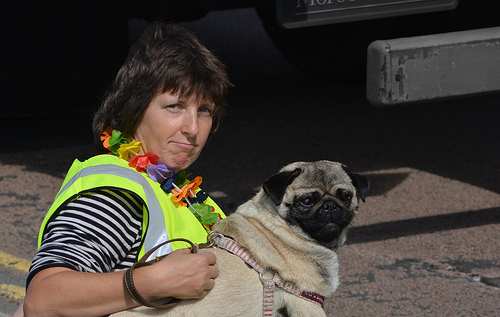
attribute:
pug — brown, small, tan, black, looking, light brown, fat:
[108, 159, 370, 316]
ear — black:
[262, 168, 302, 205]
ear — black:
[342, 164, 369, 204]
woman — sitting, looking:
[22, 21, 227, 316]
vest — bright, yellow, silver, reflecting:
[38, 155, 227, 262]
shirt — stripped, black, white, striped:
[27, 187, 145, 281]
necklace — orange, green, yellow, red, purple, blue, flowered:
[102, 126, 222, 226]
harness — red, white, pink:
[208, 233, 325, 314]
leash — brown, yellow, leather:
[124, 237, 198, 311]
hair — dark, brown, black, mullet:
[93, 24, 234, 139]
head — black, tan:
[269, 160, 367, 240]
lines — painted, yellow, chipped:
[0, 249, 34, 303]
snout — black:
[312, 199, 344, 228]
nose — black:
[321, 200, 337, 213]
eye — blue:
[163, 102, 184, 113]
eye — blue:
[198, 105, 212, 114]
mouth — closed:
[168, 139, 200, 149]